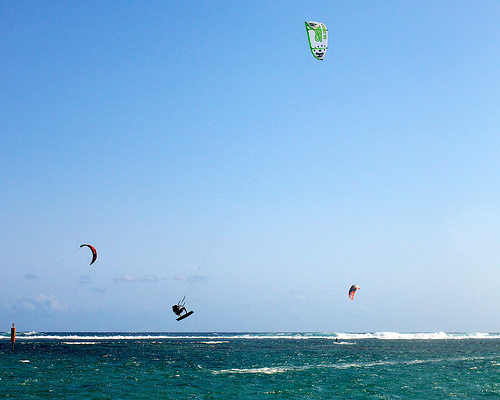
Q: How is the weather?
A: It is clear.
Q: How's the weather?
A: It is clear.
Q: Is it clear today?
A: Yes, it is clear.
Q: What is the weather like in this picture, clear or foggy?
A: It is clear.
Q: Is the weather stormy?
A: No, it is clear.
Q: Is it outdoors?
A: Yes, it is outdoors.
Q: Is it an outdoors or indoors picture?
A: It is outdoors.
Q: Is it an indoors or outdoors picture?
A: It is outdoors.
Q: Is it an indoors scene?
A: No, it is outdoors.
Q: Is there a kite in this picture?
A: Yes, there is a kite.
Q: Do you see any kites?
A: Yes, there is a kite.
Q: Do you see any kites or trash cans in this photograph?
A: Yes, there is a kite.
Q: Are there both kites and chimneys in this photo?
A: No, there is a kite but no chimneys.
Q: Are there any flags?
A: No, there are no flags.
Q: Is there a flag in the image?
A: No, there are no flags.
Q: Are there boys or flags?
A: No, there are no flags or boys.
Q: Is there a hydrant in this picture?
A: No, there are no fire hydrants.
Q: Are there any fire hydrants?
A: No, there are no fire hydrants.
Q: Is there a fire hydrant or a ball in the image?
A: No, there are no fire hydrants or balls.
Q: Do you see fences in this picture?
A: No, there are no fences.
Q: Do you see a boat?
A: No, there are no boats.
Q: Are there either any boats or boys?
A: No, there are no boats or boys.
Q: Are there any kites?
A: Yes, there is a kite.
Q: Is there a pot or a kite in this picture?
A: Yes, there is a kite.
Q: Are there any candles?
A: No, there are no candles.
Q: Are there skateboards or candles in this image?
A: No, there are no candles or skateboards.